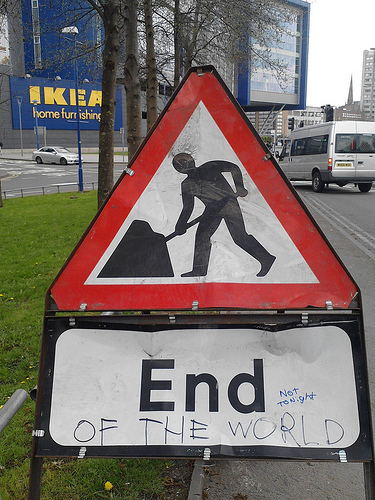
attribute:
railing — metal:
[0, 183, 100, 201]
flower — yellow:
[99, 479, 122, 498]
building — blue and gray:
[0, 0, 313, 150]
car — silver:
[31, 142, 83, 171]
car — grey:
[278, 122, 372, 190]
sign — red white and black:
[95, 77, 323, 299]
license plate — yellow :
[334, 160, 357, 168]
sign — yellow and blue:
[19, 69, 142, 140]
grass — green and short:
[1, 182, 147, 360]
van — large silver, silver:
[271, 116, 373, 194]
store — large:
[1, 1, 306, 148]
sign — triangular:
[33, 56, 367, 324]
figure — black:
[171, 149, 275, 278]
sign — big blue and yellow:
[18, 69, 127, 141]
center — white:
[90, 97, 325, 286]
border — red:
[39, 66, 362, 321]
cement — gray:
[148, 350, 363, 495]